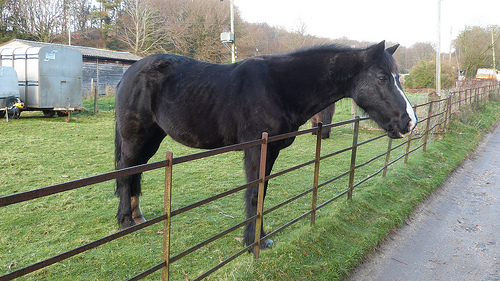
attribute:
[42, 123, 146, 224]
grass — in picture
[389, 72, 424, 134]
patch — small, white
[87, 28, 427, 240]
horse — black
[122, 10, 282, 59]
trees — dead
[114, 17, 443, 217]
horse — black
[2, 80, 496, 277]
fence — short, wooden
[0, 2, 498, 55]
sky — bright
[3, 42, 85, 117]
trailer — old, grey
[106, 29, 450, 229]
horse — black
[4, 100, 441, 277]
grass — short, green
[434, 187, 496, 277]
pavement — in picture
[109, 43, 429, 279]
horse — in picture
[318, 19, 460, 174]
head — striped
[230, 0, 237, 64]
pole — large, grey, metal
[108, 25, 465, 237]
horse — in picture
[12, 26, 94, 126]
trailer — old, grey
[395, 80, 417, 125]
white patch — in picture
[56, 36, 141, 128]
building — wooden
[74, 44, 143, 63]
roof — short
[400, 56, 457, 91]
bush — wide